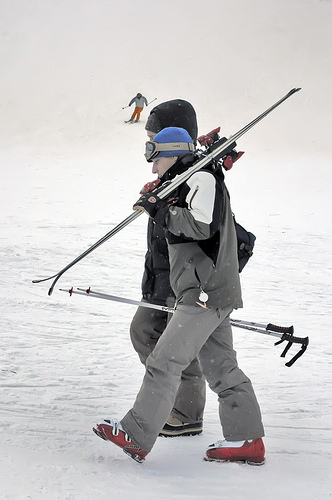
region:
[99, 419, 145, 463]
man is wearing red shoes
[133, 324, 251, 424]
man is wearing grey pants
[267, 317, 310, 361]
the top end of two ski poles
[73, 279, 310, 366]
man is carrying two snow poles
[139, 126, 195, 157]
man is wearing a blue beanie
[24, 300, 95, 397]
the white snow covers the ground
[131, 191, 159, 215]
the man is wearing black gloves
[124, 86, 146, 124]
a person is skiing in the background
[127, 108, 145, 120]
person is wearing orange pants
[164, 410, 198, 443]
man is wearing black and brown shoes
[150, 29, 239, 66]
this is the ground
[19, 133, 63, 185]
the ground is full of snow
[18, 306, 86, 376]
the snow has some tracks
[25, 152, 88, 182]
the snow is white in color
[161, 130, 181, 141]
this is a cap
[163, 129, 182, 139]
the cap is blue in color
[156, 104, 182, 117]
the cap is black in color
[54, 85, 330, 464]
these are some people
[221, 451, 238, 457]
the shoe is red in color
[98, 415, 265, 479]
the shoes rae red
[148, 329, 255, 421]
the pants are grey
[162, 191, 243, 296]
the jacket is black and grey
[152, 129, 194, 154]
the marvin is blue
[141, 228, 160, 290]
the jacket is puffed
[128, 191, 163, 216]
the glove is black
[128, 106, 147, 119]
the pants are orange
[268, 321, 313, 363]
the handle is black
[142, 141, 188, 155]
the googles are grey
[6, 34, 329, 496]
the winter is cold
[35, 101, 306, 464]
two skiers walking in the snow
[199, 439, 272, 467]
red and white ski boots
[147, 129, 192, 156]
blue ski cap and sun visor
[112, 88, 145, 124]
man skiing down ski slope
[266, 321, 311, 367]
handles to ski prongs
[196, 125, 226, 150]
clamps on skis for ski boots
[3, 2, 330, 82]
a lot of snow on top of the hill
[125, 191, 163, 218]
ski glove on mans hand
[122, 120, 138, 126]
skis omn mans foot coming down slope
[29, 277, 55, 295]
tip of skis in walking mans hand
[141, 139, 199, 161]
goggles on the man's head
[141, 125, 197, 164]
a blue hat on the man's head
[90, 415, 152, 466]
the left red shoe of the man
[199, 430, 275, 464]
the man's right red shoe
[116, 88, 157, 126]
a man wearing orange pants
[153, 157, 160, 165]
the left eye of the man wearing the blue hat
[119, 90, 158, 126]
a man skiing downhill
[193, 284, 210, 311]
a tag hanging from the pocket of the man wearing red shoes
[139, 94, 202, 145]
a black hat on a man's head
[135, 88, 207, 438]
a man wearing a black hat